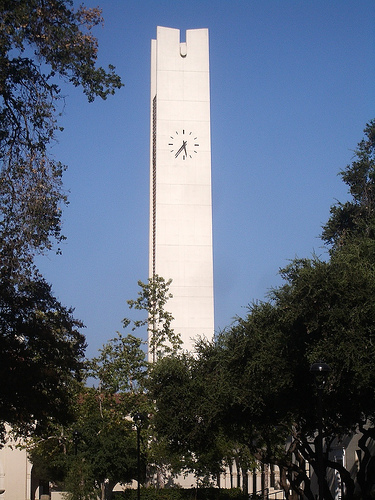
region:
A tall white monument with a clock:
[139, 24, 231, 482]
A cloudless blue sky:
[227, 32, 342, 162]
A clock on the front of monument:
[159, 120, 201, 165]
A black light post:
[131, 411, 143, 496]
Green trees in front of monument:
[148, 330, 307, 495]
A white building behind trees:
[298, 406, 370, 494]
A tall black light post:
[301, 358, 342, 493]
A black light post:
[70, 421, 85, 493]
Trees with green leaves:
[1, 3, 122, 494]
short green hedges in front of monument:
[111, 486, 254, 497]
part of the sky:
[267, 17, 318, 78]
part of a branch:
[274, 424, 317, 467]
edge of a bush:
[217, 485, 231, 491]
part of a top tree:
[101, 354, 133, 399]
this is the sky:
[245, 53, 291, 162]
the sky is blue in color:
[232, 53, 293, 138]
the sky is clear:
[232, 61, 293, 157]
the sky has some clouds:
[84, 316, 109, 335]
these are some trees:
[271, 304, 358, 490]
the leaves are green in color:
[232, 347, 309, 376]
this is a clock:
[165, 124, 204, 168]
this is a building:
[151, 22, 216, 324]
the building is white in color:
[177, 225, 198, 285]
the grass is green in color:
[210, 487, 229, 498]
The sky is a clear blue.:
[252, 45, 322, 132]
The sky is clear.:
[236, 146, 292, 221]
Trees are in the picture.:
[165, 307, 366, 493]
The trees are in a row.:
[144, 213, 369, 494]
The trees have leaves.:
[150, 213, 370, 493]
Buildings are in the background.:
[0, 382, 345, 494]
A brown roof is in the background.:
[45, 381, 150, 411]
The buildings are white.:
[127, 409, 301, 493]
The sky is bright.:
[251, 40, 334, 160]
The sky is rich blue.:
[241, 50, 319, 151]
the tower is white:
[102, 200, 297, 353]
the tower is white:
[132, 174, 220, 300]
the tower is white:
[109, 139, 226, 209]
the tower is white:
[129, 182, 180, 234]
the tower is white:
[83, 131, 363, 404]